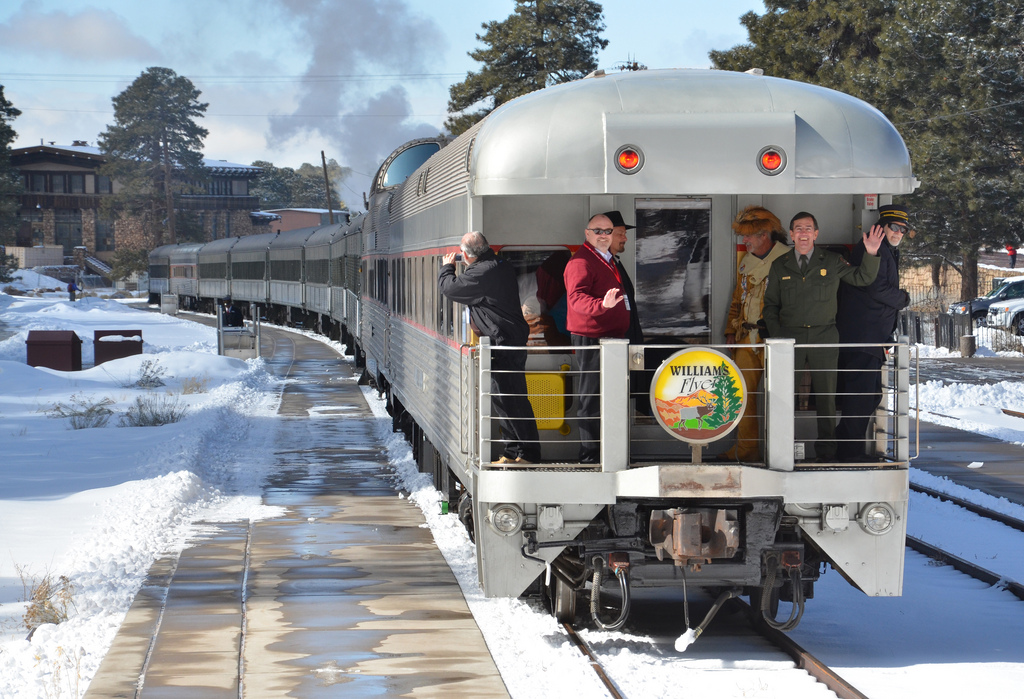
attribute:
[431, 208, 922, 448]
people — six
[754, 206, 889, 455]
man — waving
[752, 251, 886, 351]
jacket — brown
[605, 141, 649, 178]
light — red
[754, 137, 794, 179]
light — red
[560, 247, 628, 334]
jacket — red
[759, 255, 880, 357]
jacket — green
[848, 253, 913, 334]
jacket — black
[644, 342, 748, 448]
sign — colorful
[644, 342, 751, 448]
circle — yellow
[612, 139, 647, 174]
light — red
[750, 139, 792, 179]
light — red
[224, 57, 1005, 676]
train — silver, large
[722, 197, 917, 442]
man — waving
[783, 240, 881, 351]
suit — green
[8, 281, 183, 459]
trash can — black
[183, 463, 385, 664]
water — puddled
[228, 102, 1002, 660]
train — red, silver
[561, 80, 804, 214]
lights — red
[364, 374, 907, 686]
snow — white, beautiful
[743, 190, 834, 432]
uniform — green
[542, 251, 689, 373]
jacket — red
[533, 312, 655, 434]
pants — blue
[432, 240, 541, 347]
jacket — blue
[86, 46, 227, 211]
tree — tall, pine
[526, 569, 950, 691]
tracks — metal, wood